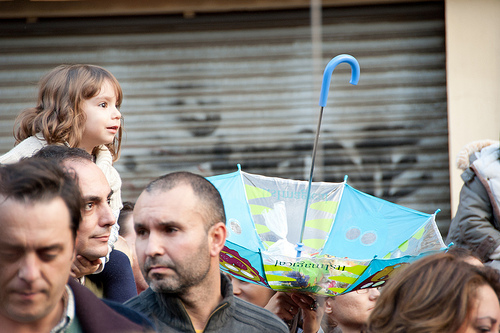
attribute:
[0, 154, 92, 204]
hair — brown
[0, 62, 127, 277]
girl — little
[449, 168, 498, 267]
sleeve — gray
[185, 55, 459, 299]
umbrella — open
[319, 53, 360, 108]
handle — blue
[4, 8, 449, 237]
door — metal